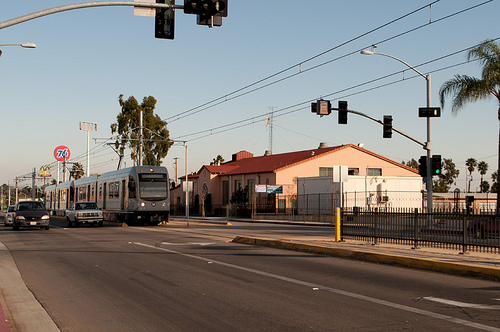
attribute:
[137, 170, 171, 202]
shield — glass, wind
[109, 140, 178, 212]
train — stopped, silver, in traffic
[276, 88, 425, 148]
lights — green, traffic, stop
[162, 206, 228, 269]
arrow — white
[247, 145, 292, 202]
signs — orange, street, walk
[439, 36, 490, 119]
trees — tall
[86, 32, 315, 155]
sky — blue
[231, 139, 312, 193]
roof — red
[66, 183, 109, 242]
truck — white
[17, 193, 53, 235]
van — black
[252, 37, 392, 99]
lines — power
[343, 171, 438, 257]
gate — iron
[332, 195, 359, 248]
pole — yellow, traffic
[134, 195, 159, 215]
headlight — on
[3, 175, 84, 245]
cars — driving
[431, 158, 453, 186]
light — green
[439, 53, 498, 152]
tree — palm, green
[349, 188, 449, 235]
fence — black, metal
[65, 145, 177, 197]
tolly — grey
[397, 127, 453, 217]
post — grey